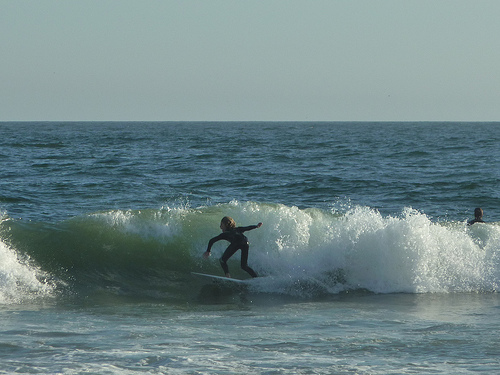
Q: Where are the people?
A: Ocean.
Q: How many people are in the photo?
A: Two.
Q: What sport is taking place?
A: Surfing.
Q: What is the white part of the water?
A: Wave.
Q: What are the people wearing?
A: Wetsuits.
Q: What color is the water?
A: Green.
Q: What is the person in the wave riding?
A: Surfboard.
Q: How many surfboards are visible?
A: One.